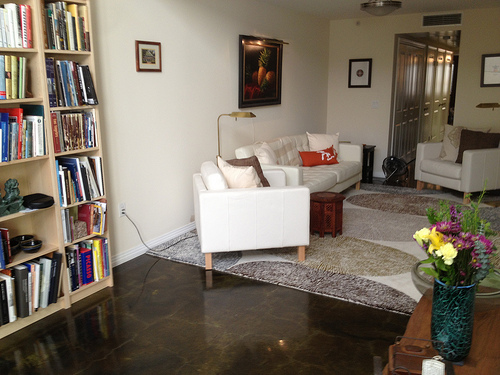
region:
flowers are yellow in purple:
[420, 211, 497, 338]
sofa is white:
[240, 107, 385, 209]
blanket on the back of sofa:
[258, 127, 309, 171]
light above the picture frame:
[240, 24, 305, 114]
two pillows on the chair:
[200, 155, 275, 194]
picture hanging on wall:
[128, 27, 170, 78]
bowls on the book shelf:
[11, 229, 45, 268]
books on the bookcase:
[21, 17, 141, 312]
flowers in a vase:
[431, 212, 498, 358]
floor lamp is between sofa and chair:
[186, 97, 271, 175]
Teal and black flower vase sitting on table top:
[428, 282, 476, 364]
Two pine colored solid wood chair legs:
[189, 248, 325, 269]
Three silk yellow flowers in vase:
[408, 228, 457, 270]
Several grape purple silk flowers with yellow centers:
[441, 212, 488, 256]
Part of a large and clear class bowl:
[411, 255, 438, 283]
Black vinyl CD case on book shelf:
[23, 190, 53, 213]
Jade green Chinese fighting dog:
[0, 175, 27, 214]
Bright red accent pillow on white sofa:
[296, 145, 338, 167]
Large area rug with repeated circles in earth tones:
[343, 182, 422, 280]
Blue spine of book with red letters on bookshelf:
[80, 248, 96, 283]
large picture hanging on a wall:
[239, 34, 284, 108]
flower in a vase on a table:
[417, 204, 485, 361]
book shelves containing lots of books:
[1, 1, 116, 306]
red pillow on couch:
[302, 145, 340, 165]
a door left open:
[397, 30, 453, 165]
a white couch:
[242, 135, 365, 189]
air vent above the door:
[422, 12, 462, 26]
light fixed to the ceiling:
[357, 0, 404, 19]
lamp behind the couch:
[215, 105, 254, 156]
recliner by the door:
[418, 121, 499, 195]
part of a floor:
[216, 302, 258, 344]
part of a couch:
[230, 192, 263, 228]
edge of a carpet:
[343, 297, 373, 319]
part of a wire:
[131, 214, 168, 231]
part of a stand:
[293, 240, 316, 272]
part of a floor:
[226, 335, 256, 369]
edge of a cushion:
[240, 165, 258, 187]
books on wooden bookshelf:
[0, 2, 98, 365]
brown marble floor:
[88, 260, 262, 372]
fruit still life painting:
[227, 20, 303, 117]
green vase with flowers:
[389, 178, 491, 368]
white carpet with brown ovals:
[321, 177, 426, 323]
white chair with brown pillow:
[182, 148, 314, 273]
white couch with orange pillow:
[257, 126, 362, 206]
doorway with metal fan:
[385, 29, 455, 200]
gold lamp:
[176, 86, 274, 167]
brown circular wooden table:
[285, 180, 372, 250]